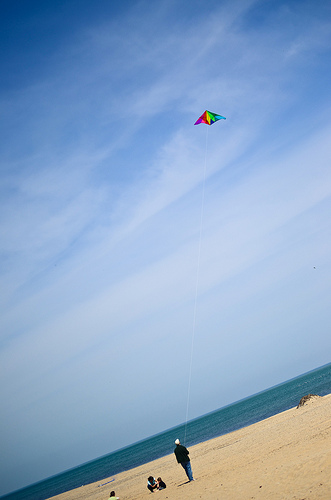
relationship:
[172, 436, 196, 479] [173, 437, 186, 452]
man wearing hat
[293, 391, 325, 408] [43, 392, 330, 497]
hill on beach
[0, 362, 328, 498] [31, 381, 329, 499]
water washing up on shore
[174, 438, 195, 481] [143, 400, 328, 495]
man on beach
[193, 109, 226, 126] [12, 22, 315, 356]
colorful kite in sky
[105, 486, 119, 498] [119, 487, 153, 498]
kite on ground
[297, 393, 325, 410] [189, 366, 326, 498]
hill in beach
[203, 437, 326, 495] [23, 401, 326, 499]
sand on beach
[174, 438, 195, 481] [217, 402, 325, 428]
man on shore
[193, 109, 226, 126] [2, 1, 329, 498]
colorful kite in blue sky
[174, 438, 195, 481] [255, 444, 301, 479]
man on beach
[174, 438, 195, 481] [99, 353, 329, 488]
man on beach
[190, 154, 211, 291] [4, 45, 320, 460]
string in air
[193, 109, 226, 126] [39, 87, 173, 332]
colorful kite in sky